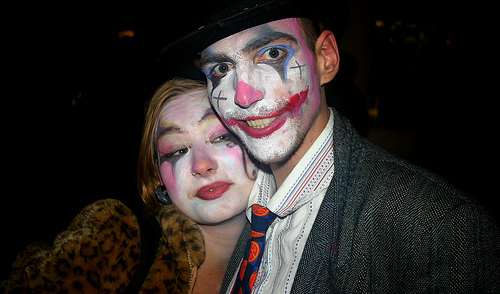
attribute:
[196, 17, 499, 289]
man — painted, posing, dressed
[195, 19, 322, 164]
face — powdered, white, painted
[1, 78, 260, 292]
woman — posing, dressed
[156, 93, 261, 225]
face — powdered, white, painted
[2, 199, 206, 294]
coat — fur, printed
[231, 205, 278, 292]
necktie — blue, orange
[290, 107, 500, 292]
jacket — grey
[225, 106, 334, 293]
shirt — white, striped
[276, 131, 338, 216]
stripes — red, blue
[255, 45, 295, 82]
outline — blue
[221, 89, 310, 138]
lipstick — red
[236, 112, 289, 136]
lips — open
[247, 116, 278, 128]
teeth — white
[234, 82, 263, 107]
nose — pink, red